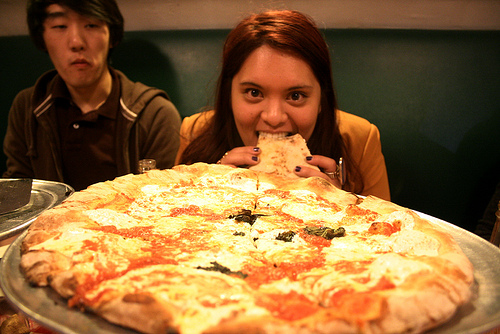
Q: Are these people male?
A: No, they are both male and female.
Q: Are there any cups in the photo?
A: No, there are no cups.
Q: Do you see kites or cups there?
A: No, there are no cups or kites.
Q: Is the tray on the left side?
A: Yes, the tray is on the left of the image.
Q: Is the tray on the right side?
A: No, the tray is on the left of the image.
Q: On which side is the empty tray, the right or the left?
A: The tray is on the left of the image.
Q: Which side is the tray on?
A: The tray is on the left of the image.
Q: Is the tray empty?
A: Yes, the tray is empty.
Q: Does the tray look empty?
A: Yes, the tray is empty.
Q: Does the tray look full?
A: No, the tray is empty.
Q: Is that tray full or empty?
A: The tray is empty.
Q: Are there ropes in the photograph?
A: No, there are no ropes.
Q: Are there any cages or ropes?
A: No, there are no ropes or cages.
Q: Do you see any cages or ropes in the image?
A: No, there are no ropes or cages.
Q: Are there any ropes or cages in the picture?
A: No, there are no ropes or cages.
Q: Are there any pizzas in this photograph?
A: Yes, there is a pizza.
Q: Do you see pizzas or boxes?
A: Yes, there is a pizza.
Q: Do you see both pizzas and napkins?
A: No, there is a pizza but no napkins.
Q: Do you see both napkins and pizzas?
A: No, there is a pizza but no napkins.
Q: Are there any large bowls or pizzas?
A: Yes, there is a large pizza.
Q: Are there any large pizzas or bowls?
A: Yes, there is a large pizza.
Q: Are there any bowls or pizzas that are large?
A: Yes, the pizza is large.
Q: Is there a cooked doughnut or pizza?
A: Yes, there is a cooked pizza.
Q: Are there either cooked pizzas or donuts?
A: Yes, there is a cooked pizza.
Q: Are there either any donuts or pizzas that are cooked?
A: Yes, the pizza is cooked.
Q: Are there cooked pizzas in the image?
A: Yes, there is a cooked pizza.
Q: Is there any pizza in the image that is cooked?
A: Yes, there is a pizza that is cooked.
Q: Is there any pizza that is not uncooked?
A: Yes, there is an cooked pizza.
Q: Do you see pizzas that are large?
A: Yes, there is a large pizza.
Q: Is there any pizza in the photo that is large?
A: Yes, there is a pizza that is large.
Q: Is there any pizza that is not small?
A: Yes, there is a large pizza.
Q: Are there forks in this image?
A: No, there are no forks.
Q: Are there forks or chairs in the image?
A: No, there are no forks or chairs.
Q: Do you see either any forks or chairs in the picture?
A: No, there are no forks or chairs.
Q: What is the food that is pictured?
A: The food is a pizza.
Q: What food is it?
A: The food is a pizza.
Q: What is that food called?
A: This is a pizza.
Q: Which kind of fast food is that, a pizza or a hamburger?
A: This is a pizza.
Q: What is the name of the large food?
A: The food is a pizza.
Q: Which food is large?
A: The food is a pizza.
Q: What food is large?
A: The food is a pizza.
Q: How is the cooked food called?
A: The food is a pizza.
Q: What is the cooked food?
A: The food is a pizza.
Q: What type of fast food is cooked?
A: The fast food is a pizza.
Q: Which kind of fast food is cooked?
A: The fast food is a pizza.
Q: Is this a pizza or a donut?
A: This is a pizza.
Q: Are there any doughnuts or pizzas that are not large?
A: No, there is a pizza but it is large.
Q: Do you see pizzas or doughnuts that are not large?
A: No, there is a pizza but it is large.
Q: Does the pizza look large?
A: Yes, the pizza is large.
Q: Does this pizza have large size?
A: Yes, the pizza is large.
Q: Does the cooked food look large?
A: Yes, the pizza is large.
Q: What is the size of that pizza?
A: The pizza is large.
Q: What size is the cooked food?
A: The pizza is large.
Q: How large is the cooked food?
A: The pizza is large.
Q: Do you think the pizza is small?
A: No, the pizza is large.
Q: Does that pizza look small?
A: No, the pizza is large.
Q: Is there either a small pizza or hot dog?
A: No, there is a pizza but it is large.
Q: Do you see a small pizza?
A: No, there is a pizza but it is large.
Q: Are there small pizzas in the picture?
A: No, there is a pizza but it is large.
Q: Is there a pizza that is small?
A: No, there is a pizza but it is large.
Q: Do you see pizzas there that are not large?
A: No, there is a pizza but it is large.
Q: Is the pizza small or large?
A: The pizza is large.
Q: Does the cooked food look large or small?
A: The pizza is large.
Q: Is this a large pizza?
A: Yes, this is a large pizza.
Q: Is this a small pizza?
A: No, this is a large pizza.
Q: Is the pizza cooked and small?
A: No, the pizza is cooked but large.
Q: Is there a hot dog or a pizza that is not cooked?
A: No, there is a pizza but it is cooked.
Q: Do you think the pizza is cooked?
A: Yes, the pizza is cooked.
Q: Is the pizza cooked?
A: Yes, the pizza is cooked.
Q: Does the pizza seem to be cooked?
A: Yes, the pizza is cooked.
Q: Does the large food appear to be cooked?
A: Yes, the pizza is cooked.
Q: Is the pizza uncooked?
A: No, the pizza is cooked.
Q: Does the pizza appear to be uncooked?
A: No, the pizza is cooked.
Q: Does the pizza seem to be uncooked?
A: No, the pizza is cooked.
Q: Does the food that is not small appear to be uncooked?
A: No, the pizza is cooked.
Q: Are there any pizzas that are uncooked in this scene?
A: No, there is a pizza but it is cooked.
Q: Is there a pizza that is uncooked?
A: No, there is a pizza but it is cooked.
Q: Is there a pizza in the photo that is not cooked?
A: No, there is a pizza but it is cooked.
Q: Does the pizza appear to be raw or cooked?
A: The pizza is cooked.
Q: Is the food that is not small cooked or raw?
A: The pizza is cooked.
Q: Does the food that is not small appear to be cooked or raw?
A: The pizza is cooked.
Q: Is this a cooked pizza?
A: Yes, this is a cooked pizza.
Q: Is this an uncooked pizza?
A: No, this is a cooked pizza.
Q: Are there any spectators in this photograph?
A: No, there are no spectators.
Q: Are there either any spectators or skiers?
A: No, there are no spectators or skiers.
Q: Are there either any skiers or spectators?
A: No, there are no spectators or skiers.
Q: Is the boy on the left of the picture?
A: Yes, the boy is on the left of the image.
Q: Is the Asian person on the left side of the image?
A: Yes, the boy is on the left of the image.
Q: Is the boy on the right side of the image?
A: No, the boy is on the left of the image.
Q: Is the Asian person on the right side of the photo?
A: No, the boy is on the left of the image.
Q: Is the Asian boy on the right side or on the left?
A: The boy is on the left of the image.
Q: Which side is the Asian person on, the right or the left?
A: The boy is on the left of the image.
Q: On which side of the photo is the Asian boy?
A: The boy is on the left of the image.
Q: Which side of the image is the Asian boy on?
A: The boy is on the left of the image.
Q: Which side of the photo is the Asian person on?
A: The boy is on the left of the image.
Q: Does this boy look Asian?
A: Yes, the boy is asian.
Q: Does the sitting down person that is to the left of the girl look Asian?
A: Yes, the boy is asian.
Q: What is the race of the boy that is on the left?
A: The boy is asian.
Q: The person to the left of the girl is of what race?
A: The boy is asian.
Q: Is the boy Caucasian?
A: No, the boy is asian.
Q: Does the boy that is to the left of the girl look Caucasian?
A: No, the boy is asian.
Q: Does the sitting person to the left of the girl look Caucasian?
A: No, the boy is asian.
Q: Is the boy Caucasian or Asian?
A: The boy is asian.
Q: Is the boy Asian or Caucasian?
A: The boy is asian.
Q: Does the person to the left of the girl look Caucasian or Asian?
A: The boy is asian.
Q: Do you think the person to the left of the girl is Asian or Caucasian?
A: The boy is asian.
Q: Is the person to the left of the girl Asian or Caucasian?
A: The boy is asian.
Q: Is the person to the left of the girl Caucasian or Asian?
A: The boy is asian.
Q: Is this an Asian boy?
A: Yes, this is an Asian boy.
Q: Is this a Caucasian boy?
A: No, this is an Asian boy.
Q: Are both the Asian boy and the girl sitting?
A: Yes, both the boy and the girl are sitting.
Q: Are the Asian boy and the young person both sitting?
A: Yes, both the boy and the girl are sitting.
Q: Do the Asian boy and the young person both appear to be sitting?
A: Yes, both the boy and the girl are sitting.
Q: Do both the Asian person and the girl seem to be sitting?
A: Yes, both the boy and the girl are sitting.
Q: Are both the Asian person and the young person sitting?
A: Yes, both the boy and the girl are sitting.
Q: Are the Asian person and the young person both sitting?
A: Yes, both the boy and the girl are sitting.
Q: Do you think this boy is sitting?
A: Yes, the boy is sitting.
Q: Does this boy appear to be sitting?
A: Yes, the boy is sitting.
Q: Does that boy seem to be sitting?
A: Yes, the boy is sitting.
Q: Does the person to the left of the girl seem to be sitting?
A: Yes, the boy is sitting.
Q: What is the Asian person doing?
A: The boy is sitting.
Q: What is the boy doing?
A: The boy is sitting.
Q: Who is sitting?
A: The boy is sitting.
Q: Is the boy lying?
A: No, the boy is sitting.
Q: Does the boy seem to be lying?
A: No, the boy is sitting.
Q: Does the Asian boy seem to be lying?
A: No, the boy is sitting.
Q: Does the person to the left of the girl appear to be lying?
A: No, the boy is sitting.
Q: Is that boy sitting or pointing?
A: The boy is sitting.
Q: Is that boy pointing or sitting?
A: The boy is sitting.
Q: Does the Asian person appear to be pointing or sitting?
A: The boy is sitting.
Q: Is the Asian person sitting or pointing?
A: The boy is sitting.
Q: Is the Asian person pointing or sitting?
A: The boy is sitting.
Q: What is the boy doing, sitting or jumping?
A: The boy is sitting.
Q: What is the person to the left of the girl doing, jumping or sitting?
A: The boy is sitting.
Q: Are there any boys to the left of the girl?
A: Yes, there is a boy to the left of the girl.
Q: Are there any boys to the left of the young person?
A: Yes, there is a boy to the left of the girl.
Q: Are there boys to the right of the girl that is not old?
A: No, the boy is to the left of the girl.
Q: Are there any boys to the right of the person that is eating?
A: No, the boy is to the left of the girl.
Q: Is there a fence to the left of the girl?
A: No, there is a boy to the left of the girl.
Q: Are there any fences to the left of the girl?
A: No, there is a boy to the left of the girl.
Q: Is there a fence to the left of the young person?
A: No, there is a boy to the left of the girl.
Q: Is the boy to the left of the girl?
A: Yes, the boy is to the left of the girl.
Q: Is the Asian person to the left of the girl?
A: Yes, the boy is to the left of the girl.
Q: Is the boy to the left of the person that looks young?
A: Yes, the boy is to the left of the girl.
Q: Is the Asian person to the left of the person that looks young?
A: Yes, the boy is to the left of the girl.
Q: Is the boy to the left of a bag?
A: No, the boy is to the left of the girl.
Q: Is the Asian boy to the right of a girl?
A: No, the boy is to the left of a girl.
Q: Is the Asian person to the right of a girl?
A: No, the boy is to the left of a girl.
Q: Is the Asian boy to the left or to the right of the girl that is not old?
A: The boy is to the left of the girl.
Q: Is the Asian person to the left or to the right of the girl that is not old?
A: The boy is to the left of the girl.